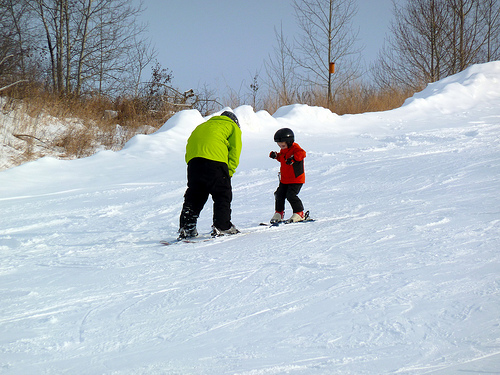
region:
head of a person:
[266, 109, 300, 146]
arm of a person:
[283, 146, 313, 170]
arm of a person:
[256, 139, 287, 170]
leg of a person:
[286, 175, 306, 217]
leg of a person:
[262, 186, 289, 216]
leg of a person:
[197, 162, 252, 240]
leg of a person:
[177, 172, 209, 232]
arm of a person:
[225, 136, 256, 176]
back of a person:
[180, 123, 232, 161]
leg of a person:
[173, 222, 201, 249]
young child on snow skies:
[257, 127, 313, 224]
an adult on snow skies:
[166, 111, 247, 251]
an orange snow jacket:
[274, 145, 306, 184]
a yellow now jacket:
[185, 115, 240, 174]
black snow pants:
[183, 158, 231, 227]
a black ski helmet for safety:
[274, 129, 296, 146]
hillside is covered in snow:
[7, 162, 497, 372]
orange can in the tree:
[327, 64, 334, 71]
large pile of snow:
[412, 61, 497, 111]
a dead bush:
[53, 126, 93, 153]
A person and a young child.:
[155, 97, 342, 248]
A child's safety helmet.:
[265, 118, 302, 153]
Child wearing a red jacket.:
[264, 119, 313, 185]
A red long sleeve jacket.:
[271, 145, 309, 187]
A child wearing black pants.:
[268, 129, 315, 231]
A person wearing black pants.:
[173, 94, 246, 244]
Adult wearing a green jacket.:
[181, 111, 244, 168]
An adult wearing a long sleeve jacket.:
[177, 110, 245, 168]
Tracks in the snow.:
[26, 115, 476, 363]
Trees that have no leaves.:
[15, 1, 487, 111]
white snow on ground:
[46, 230, 84, 265]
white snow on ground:
[80, 301, 107, 323]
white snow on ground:
[113, 285, 150, 312]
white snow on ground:
[153, 266, 198, 303]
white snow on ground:
[220, 286, 250, 316]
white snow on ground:
[255, 258, 296, 305]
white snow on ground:
[296, 306, 336, 345]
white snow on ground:
[319, 266, 381, 356]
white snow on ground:
[344, 238, 393, 281]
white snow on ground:
[393, 195, 435, 229]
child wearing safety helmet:
[254, 102, 324, 255]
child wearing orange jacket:
[263, 109, 314, 234]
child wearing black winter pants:
[250, 95, 324, 242]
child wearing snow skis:
[241, 121, 321, 248]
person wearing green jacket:
[153, 98, 256, 286]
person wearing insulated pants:
[146, 103, 256, 273]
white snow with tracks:
[73, 251, 392, 351]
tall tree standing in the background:
[315, 0, 340, 124]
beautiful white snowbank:
[318, 61, 483, 138]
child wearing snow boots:
[256, 114, 310, 254]